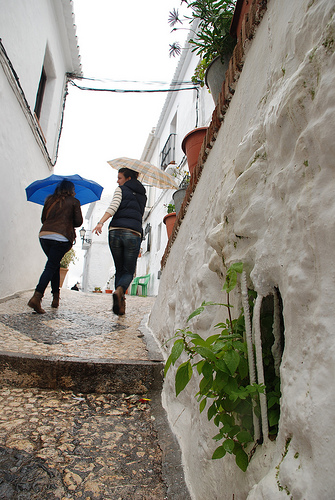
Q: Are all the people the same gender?
A: Yes, all the people are female.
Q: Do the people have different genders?
A: No, all the people are female.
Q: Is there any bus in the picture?
A: No, there are no buses.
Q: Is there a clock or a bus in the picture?
A: No, there are no buses or clocks.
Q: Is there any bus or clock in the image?
A: No, there are no buses or clocks.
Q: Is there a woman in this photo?
A: Yes, there are women.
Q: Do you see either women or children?
A: Yes, there are women.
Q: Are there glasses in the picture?
A: No, there are no glasses.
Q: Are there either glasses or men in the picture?
A: No, there are no glasses or men.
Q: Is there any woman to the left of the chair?
A: Yes, there are women to the left of the chair.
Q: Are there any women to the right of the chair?
A: No, the women are to the left of the chair.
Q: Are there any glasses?
A: No, there are no glasses.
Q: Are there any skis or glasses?
A: No, there are no glasses or skis.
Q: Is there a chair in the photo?
A: Yes, there is a chair.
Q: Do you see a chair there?
A: Yes, there is a chair.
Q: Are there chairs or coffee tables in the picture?
A: Yes, there is a chair.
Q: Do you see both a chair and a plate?
A: No, there is a chair but no plates.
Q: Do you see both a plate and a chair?
A: No, there is a chair but no plates.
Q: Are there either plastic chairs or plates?
A: Yes, there is a plastic chair.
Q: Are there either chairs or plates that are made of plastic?
A: Yes, the chair is made of plastic.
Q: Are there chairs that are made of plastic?
A: Yes, there is a chair that is made of plastic.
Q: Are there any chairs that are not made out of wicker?
A: Yes, there is a chair that is made of plastic.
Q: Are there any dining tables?
A: No, there are no dining tables.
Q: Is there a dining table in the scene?
A: No, there are no dining tables.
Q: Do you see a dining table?
A: No, there are no dining tables.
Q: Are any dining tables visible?
A: No, there are no dining tables.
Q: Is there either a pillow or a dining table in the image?
A: No, there are no dining tables or pillows.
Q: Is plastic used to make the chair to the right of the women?
A: Yes, the chair is made of plastic.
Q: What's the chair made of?
A: The chair is made of plastic.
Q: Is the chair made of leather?
A: No, the chair is made of plastic.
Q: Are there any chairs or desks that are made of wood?
A: No, there is a chair but it is made of plastic.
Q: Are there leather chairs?
A: No, there is a chair but it is made of plastic.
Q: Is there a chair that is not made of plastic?
A: No, there is a chair but it is made of plastic.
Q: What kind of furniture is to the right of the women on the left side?
A: The piece of furniture is a chair.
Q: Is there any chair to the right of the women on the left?
A: Yes, there is a chair to the right of the women.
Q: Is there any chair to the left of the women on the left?
A: No, the chair is to the right of the women.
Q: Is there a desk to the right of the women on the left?
A: No, there is a chair to the right of the women.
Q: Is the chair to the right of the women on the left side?
A: Yes, the chair is to the right of the women.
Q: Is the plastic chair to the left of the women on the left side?
A: No, the chair is to the right of the women.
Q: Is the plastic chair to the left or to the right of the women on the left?
A: The chair is to the right of the women.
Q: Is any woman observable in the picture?
A: Yes, there is a woman.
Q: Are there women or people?
A: Yes, there is a woman.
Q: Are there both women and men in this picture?
A: No, there is a woman but no men.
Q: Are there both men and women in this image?
A: No, there is a woman but no men.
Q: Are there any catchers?
A: No, there are no catchers.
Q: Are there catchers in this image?
A: No, there are no catchers.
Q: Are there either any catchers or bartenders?
A: No, there are no catchers or bartenders.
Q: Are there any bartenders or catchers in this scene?
A: No, there are no catchers or bartenders.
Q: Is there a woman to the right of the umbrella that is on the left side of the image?
A: Yes, there is a woman to the right of the umbrella.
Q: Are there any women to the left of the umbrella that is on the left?
A: No, the woman is to the right of the umbrella.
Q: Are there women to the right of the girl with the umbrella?
A: Yes, there is a woman to the right of the girl.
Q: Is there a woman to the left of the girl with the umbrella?
A: No, the woman is to the right of the girl.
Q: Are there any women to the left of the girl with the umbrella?
A: No, the woman is to the right of the girl.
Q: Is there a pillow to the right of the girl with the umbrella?
A: No, there is a woman to the right of the girl.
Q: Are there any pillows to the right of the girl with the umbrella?
A: No, there is a woman to the right of the girl.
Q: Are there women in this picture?
A: Yes, there are women.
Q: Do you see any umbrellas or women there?
A: Yes, there are women.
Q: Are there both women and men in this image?
A: No, there are women but no men.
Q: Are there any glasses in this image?
A: No, there are no glasses.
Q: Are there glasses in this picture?
A: No, there are no glasses.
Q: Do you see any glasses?
A: No, there are no glasses.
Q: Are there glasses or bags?
A: No, there are no glasses or bags.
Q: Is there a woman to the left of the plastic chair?
A: Yes, there are women to the left of the chair.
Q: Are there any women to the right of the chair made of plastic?
A: No, the women are to the left of the chair.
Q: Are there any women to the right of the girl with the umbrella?
A: Yes, there are women to the right of the girl.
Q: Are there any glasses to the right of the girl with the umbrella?
A: No, there are women to the right of the girl.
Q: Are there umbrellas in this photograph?
A: Yes, there is an umbrella.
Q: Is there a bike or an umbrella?
A: Yes, there is an umbrella.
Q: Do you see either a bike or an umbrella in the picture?
A: Yes, there is an umbrella.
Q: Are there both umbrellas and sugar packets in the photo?
A: No, there is an umbrella but no sugar packets.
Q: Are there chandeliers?
A: No, there are no chandeliers.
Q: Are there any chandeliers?
A: No, there are no chandeliers.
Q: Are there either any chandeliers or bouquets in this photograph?
A: No, there are no chandeliers or bouquets.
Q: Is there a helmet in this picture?
A: No, there are no helmets.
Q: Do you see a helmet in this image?
A: No, there are no helmets.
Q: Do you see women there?
A: Yes, there is a woman.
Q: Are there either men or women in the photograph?
A: Yes, there is a woman.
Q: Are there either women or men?
A: Yes, there is a woman.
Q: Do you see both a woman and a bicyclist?
A: No, there is a woman but no cyclists.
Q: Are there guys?
A: No, there are no guys.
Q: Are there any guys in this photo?
A: No, there are no guys.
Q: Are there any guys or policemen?
A: No, there are no guys or policemen.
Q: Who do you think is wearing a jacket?
A: The woman is wearing a jacket.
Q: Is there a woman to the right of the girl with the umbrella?
A: Yes, there is a woman to the right of the girl.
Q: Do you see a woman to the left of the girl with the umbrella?
A: No, the woman is to the right of the girl.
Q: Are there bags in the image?
A: No, there are no bags.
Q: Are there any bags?
A: No, there are no bags.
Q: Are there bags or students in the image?
A: No, there are no bags or students.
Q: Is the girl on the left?
A: Yes, the girl is on the left of the image.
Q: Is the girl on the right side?
A: No, the girl is on the left of the image.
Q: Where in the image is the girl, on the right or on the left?
A: The girl is on the left of the image.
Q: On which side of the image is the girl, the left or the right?
A: The girl is on the left of the image.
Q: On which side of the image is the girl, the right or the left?
A: The girl is on the left of the image.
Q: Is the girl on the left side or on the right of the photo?
A: The girl is on the left of the image.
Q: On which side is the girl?
A: The girl is on the left of the image.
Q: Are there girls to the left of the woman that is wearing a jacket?
A: Yes, there is a girl to the left of the woman.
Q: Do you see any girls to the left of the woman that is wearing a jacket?
A: Yes, there is a girl to the left of the woman.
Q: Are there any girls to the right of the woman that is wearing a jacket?
A: No, the girl is to the left of the woman.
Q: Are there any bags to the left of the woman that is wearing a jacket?
A: No, there is a girl to the left of the woman.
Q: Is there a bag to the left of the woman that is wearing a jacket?
A: No, there is a girl to the left of the woman.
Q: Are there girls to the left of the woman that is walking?
A: Yes, there is a girl to the left of the woman.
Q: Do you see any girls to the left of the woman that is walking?
A: Yes, there is a girl to the left of the woman.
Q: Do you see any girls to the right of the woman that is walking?
A: No, the girl is to the left of the woman.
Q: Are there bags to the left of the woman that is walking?
A: No, there is a girl to the left of the woman.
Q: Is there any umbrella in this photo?
A: Yes, there is an umbrella.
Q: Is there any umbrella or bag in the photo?
A: Yes, there is an umbrella.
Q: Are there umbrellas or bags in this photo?
A: Yes, there is an umbrella.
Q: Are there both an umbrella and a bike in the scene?
A: No, there is an umbrella but no bikes.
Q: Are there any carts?
A: No, there are no carts.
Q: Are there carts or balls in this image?
A: No, there are no carts or balls.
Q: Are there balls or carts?
A: No, there are no carts or balls.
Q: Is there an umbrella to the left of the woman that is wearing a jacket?
A: Yes, there is an umbrella to the left of the woman.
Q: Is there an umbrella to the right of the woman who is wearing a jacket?
A: No, the umbrella is to the left of the woman.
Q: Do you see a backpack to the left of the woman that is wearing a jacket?
A: No, there is an umbrella to the left of the woman.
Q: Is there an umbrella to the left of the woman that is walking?
A: Yes, there is an umbrella to the left of the woman.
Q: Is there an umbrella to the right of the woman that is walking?
A: No, the umbrella is to the left of the woman.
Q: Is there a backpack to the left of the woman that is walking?
A: No, there is an umbrella to the left of the woman.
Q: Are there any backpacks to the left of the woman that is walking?
A: No, there is an umbrella to the left of the woman.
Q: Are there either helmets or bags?
A: No, there are no bags or helmets.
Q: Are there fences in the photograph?
A: Yes, there is a fence.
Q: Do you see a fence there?
A: Yes, there is a fence.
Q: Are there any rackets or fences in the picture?
A: Yes, there is a fence.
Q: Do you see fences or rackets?
A: Yes, there is a fence.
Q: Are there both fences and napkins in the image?
A: No, there is a fence but no napkins.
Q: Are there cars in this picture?
A: No, there are no cars.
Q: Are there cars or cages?
A: No, there are no cars or cages.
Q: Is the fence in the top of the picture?
A: Yes, the fence is in the top of the image.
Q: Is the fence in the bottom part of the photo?
A: No, the fence is in the top of the image.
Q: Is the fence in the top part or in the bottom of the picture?
A: The fence is in the top of the image.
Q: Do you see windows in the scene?
A: Yes, there is a window.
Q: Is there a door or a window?
A: Yes, there is a window.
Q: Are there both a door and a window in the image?
A: No, there is a window but no doors.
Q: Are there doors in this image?
A: No, there are no doors.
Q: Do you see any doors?
A: No, there are no doors.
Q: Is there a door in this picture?
A: No, there are no doors.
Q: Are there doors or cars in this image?
A: No, there are no doors or cars.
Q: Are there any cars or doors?
A: No, there are no doors or cars.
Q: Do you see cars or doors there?
A: No, there are no doors or cars.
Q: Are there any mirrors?
A: No, there are no mirrors.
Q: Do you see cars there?
A: No, there are no cars.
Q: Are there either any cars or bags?
A: No, there are no cars or bags.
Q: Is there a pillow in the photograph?
A: No, there are no pillows.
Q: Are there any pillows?
A: No, there are no pillows.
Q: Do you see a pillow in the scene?
A: No, there are no pillows.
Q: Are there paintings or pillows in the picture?
A: No, there are no pillows or paintings.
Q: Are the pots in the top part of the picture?
A: Yes, the pots are in the top of the image.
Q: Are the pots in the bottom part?
A: No, the pots are in the top of the image.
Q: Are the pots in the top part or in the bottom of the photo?
A: The pots are in the top of the image.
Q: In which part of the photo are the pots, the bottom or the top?
A: The pots are in the top of the image.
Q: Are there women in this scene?
A: Yes, there is a woman.